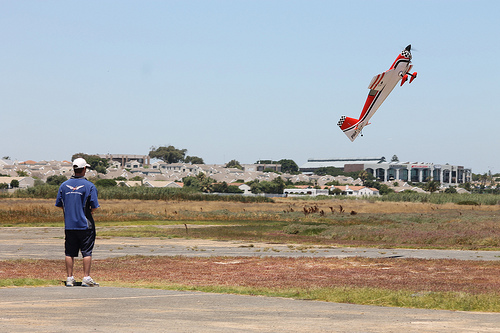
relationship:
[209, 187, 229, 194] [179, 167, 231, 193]
green leaf on a plant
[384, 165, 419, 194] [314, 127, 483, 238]
window on building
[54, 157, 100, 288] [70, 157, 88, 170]
man wearing hat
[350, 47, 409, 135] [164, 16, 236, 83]
plane in air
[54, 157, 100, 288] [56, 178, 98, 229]
man wearing a shirt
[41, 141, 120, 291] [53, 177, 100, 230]
man wearing a shirt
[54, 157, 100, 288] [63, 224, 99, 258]
man wearing black shorts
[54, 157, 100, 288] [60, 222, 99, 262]
man wearing black shorts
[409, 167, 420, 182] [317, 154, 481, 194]
window on building